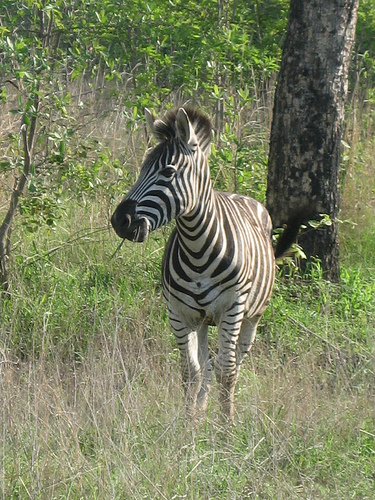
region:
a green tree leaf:
[56, 137, 66, 155]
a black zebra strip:
[172, 280, 197, 296]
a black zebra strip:
[193, 280, 221, 299]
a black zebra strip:
[173, 293, 194, 313]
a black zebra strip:
[167, 313, 181, 323]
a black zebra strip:
[169, 326, 188, 339]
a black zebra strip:
[170, 324, 185, 332]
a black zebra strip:
[226, 317, 244, 325]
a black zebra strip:
[223, 336, 236, 345]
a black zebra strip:
[223, 355, 238, 364]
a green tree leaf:
[28, 159, 37, 168]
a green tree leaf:
[309, 218, 319, 229]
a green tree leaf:
[322, 214, 332, 229]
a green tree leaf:
[45, 211, 55, 223]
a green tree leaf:
[131, 105, 139, 122]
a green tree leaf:
[213, 81, 221, 93]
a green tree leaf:
[239, 85, 254, 103]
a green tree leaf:
[5, 33, 17, 52]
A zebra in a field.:
[102, 90, 284, 420]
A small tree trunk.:
[265, 1, 343, 277]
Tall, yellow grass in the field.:
[1, 311, 157, 499]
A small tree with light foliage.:
[0, 104, 105, 235]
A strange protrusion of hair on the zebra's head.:
[136, 100, 214, 155]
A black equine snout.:
[103, 193, 153, 247]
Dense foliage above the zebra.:
[96, 0, 287, 84]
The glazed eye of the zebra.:
[155, 163, 178, 180]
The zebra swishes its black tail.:
[270, 208, 311, 261]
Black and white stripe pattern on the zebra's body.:
[224, 216, 272, 286]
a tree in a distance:
[13, 31, 58, 179]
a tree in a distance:
[70, 151, 109, 228]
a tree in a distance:
[206, 25, 252, 161]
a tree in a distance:
[278, 1, 348, 269]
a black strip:
[168, 316, 185, 325]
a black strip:
[227, 310, 245, 315]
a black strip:
[222, 318, 251, 326]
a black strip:
[222, 333, 241, 346]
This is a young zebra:
[89, 93, 286, 442]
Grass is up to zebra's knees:
[9, 256, 365, 498]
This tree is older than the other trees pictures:
[263, 1, 361, 295]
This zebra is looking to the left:
[98, 93, 217, 263]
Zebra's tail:
[261, 181, 327, 269]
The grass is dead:
[0, 305, 369, 495]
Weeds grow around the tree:
[259, 192, 342, 295]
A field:
[4, 334, 374, 493]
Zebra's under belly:
[174, 298, 256, 344]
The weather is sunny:
[2, 1, 360, 497]